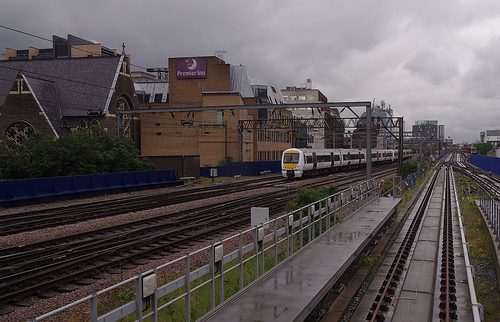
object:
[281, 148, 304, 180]
front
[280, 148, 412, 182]
train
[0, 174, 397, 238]
tracks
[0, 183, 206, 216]
gravel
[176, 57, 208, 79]
sign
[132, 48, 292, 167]
building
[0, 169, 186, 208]
barrier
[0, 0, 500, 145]
sky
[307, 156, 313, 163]
windows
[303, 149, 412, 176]
side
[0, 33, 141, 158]
building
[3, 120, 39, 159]
window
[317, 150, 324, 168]
passangers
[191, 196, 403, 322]
bench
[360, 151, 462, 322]
tracks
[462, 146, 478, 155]
trolley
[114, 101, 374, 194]
signal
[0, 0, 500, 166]
background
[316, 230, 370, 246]
puddles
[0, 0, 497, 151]
rain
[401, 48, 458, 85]
clouds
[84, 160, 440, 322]
grass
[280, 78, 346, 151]
buildings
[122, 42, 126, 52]
cross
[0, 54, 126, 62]
top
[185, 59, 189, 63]
star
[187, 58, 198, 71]
moon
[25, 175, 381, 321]
railing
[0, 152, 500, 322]
sets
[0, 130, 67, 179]
trees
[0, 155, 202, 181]
wall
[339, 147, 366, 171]
car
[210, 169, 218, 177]
sign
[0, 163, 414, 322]
train tracks